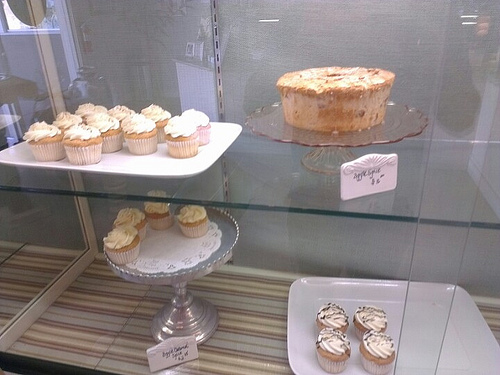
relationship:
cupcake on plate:
[163, 121, 198, 153] [106, 154, 194, 179]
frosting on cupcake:
[67, 128, 100, 141] [64, 143, 100, 163]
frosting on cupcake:
[181, 208, 205, 220] [182, 222, 209, 237]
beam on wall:
[212, 4, 228, 124] [104, 3, 333, 67]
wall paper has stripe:
[62, 290, 127, 341] [65, 302, 95, 315]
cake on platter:
[286, 74, 381, 130] [132, 232, 241, 274]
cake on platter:
[286, 74, 381, 130] [264, 132, 418, 150]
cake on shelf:
[286, 74, 381, 130] [240, 157, 310, 200]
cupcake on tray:
[319, 307, 346, 326] [396, 293, 477, 369]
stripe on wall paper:
[232, 330, 251, 340] [62, 290, 127, 341]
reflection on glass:
[464, 31, 494, 82] [94, 5, 464, 40]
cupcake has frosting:
[319, 329, 354, 370] [323, 332, 335, 338]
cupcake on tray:
[367, 352, 392, 371] [396, 293, 477, 369]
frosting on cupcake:
[369, 338, 387, 354] [367, 352, 392, 371]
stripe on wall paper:
[234, 274, 276, 282] [62, 290, 127, 341]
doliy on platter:
[145, 234, 198, 265] [132, 232, 241, 274]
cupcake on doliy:
[149, 211, 176, 230] [145, 234, 198, 265]